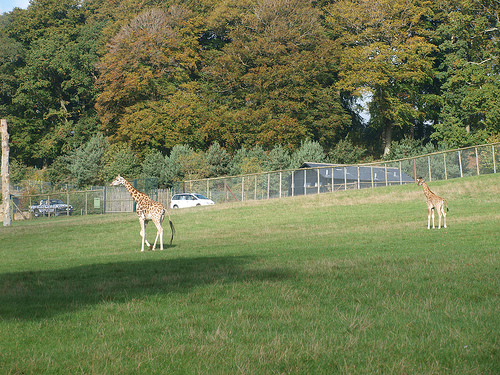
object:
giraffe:
[112, 175, 175, 252]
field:
[1, 171, 499, 374]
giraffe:
[415, 178, 452, 231]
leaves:
[96, 3, 433, 145]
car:
[171, 194, 212, 211]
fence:
[9, 141, 498, 225]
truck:
[31, 200, 73, 218]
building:
[286, 163, 420, 201]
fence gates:
[104, 182, 173, 215]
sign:
[92, 197, 102, 209]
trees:
[3, 3, 499, 200]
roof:
[309, 159, 416, 184]